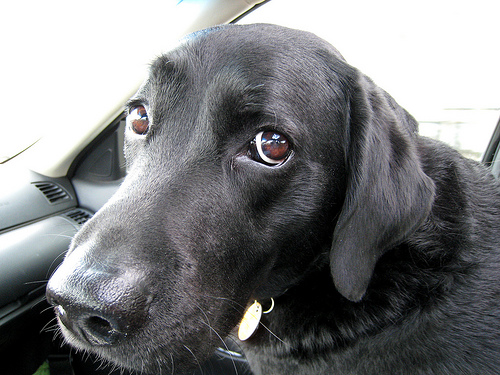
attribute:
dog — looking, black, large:
[46, 22, 499, 374]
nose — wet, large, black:
[45, 266, 152, 349]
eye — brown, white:
[248, 130, 294, 168]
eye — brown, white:
[123, 103, 152, 138]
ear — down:
[328, 74, 437, 302]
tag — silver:
[238, 301, 263, 342]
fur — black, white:
[46, 23, 499, 374]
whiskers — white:
[26, 273, 285, 373]